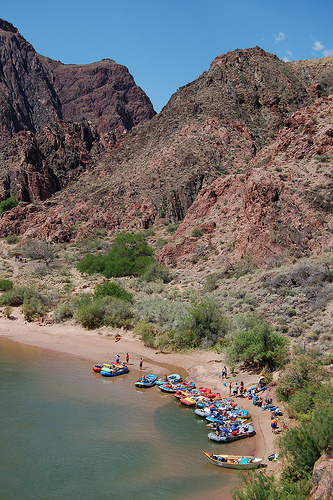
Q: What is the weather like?
A: Sunny.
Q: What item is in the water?
A: Rafts.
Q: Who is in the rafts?
A: Men and women.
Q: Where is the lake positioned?
A: In the hills.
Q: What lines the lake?
A: Trees.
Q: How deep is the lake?
A: Shallow.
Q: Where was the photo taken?
A: At the lake.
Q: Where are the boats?
A: At the shore.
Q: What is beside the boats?
A: Water.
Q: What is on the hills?
A: Grass.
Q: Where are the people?
A: In the boat.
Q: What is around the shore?
A: Trees.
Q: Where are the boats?
A: The boats are on the shore.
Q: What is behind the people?
A: There are mountains and brush behind the people.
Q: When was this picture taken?
A: This picture was taken during the day.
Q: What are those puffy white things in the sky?
A: There are clouds in the sky.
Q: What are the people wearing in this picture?
A: The people are wearing bathing suits and t-shirts.